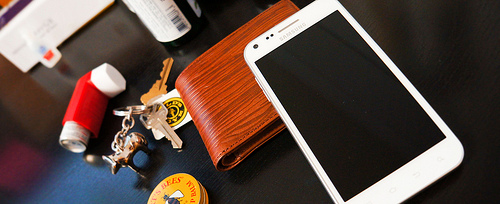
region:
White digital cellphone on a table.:
[242, 0, 462, 201]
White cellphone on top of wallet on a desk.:
[175, 1, 463, 201]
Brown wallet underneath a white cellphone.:
[176, 0, 301, 171]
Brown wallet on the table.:
[175, 1, 298, 173]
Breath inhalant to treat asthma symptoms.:
[57, 60, 127, 152]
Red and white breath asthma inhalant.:
[57, 61, 126, 154]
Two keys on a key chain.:
[106, 52, 188, 174]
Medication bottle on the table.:
[115, 0, 210, 52]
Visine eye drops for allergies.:
[20, 30, 64, 73]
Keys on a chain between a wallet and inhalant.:
[102, 57, 191, 173]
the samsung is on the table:
[227, 32, 464, 202]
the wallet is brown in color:
[166, 46, 308, 154]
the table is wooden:
[18, 123, 53, 190]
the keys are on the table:
[106, 101, 175, 146]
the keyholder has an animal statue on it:
[101, 141, 154, 176]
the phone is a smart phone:
[246, 23, 439, 202]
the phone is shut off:
[244, 27, 463, 192]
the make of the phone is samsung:
[243, 31, 469, 193]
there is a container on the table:
[139, 1, 207, 35]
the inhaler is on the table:
[60, 68, 133, 155]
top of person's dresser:
[2, 0, 498, 202]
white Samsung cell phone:
[241, 0, 463, 202]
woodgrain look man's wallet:
[174, 1, 299, 171]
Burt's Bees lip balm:
[141, 173, 210, 203]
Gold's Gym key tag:
[143, 89, 191, 138]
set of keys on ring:
[102, 57, 184, 179]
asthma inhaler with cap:
[55, 61, 127, 153]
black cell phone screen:
[253, 9, 445, 200]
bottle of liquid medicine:
[122, 0, 212, 55]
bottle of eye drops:
[19, 26, 61, 66]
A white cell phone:
[222, 21, 464, 190]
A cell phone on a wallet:
[232, 24, 426, 126]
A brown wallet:
[223, 32, 330, 155]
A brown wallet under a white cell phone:
[208, 26, 365, 145]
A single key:
[133, 97, 183, 151]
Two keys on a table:
[131, 48, 186, 159]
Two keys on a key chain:
[99, 65, 187, 174]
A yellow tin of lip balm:
[112, 165, 229, 201]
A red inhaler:
[38, 63, 145, 162]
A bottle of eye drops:
[13, 21, 65, 79]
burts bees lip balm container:
[138, 171, 216, 199]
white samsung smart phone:
[243, 0, 467, 202]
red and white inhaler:
[52, 66, 139, 183]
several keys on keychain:
[87, 53, 205, 195]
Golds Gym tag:
[146, 90, 205, 142]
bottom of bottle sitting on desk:
[109, 1, 211, 47]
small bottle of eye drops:
[17, 24, 71, 67]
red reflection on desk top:
[9, 85, 61, 191]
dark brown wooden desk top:
[420, 20, 498, 107]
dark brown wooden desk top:
[231, 169, 303, 202]